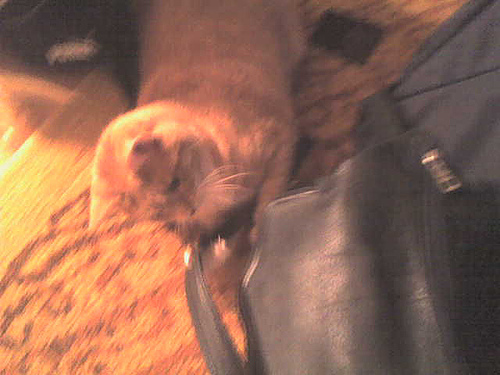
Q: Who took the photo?
A: Owner.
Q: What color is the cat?
A: Orange.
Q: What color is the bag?
A: Black.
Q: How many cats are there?
A: 1.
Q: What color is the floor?
A: Wood.